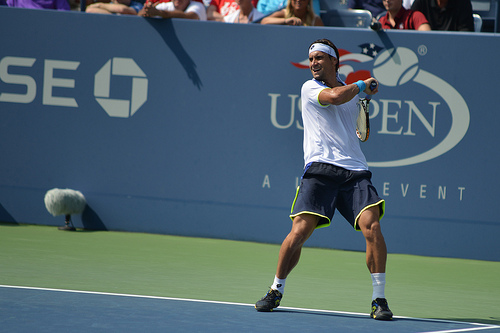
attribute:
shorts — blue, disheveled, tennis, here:
[284, 163, 387, 230]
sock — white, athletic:
[267, 278, 287, 296]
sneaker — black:
[256, 287, 284, 314]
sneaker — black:
[365, 297, 394, 321]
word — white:
[3, 52, 150, 117]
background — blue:
[5, 3, 498, 232]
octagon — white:
[89, 53, 153, 116]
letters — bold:
[0, 53, 88, 107]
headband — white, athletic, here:
[308, 42, 340, 59]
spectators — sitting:
[5, 0, 498, 36]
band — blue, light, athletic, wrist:
[357, 77, 365, 94]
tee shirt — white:
[300, 78, 377, 174]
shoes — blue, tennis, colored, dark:
[251, 295, 398, 322]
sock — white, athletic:
[370, 270, 388, 302]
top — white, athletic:
[298, 77, 369, 172]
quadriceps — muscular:
[333, 84, 361, 104]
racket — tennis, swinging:
[354, 78, 379, 141]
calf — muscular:
[278, 239, 304, 277]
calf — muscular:
[364, 237, 390, 277]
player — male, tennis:
[251, 37, 397, 320]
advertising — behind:
[1, 38, 483, 209]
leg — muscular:
[271, 216, 320, 285]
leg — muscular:
[358, 207, 386, 272]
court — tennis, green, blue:
[5, 7, 498, 326]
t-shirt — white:
[299, 77, 372, 172]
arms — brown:
[317, 77, 382, 124]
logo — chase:
[1, 43, 160, 117]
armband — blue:
[354, 80, 370, 97]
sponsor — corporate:
[2, 53, 149, 120]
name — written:
[259, 41, 491, 210]